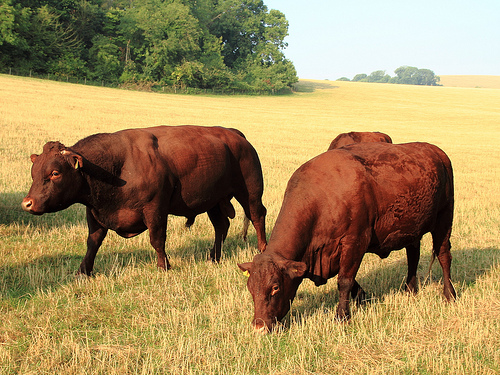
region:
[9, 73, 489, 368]
cows in the meadow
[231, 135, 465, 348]
cow is eating grass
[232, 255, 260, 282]
yellow tag on ear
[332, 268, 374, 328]
front legs of cow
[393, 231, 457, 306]
back legs of cow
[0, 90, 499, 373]
dry grass in the field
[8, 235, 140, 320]
shadow cast on the grass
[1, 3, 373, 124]
green trees on side of field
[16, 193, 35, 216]
nostrils of cow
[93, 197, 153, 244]
brisket of cow is bulky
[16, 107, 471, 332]
brown cows in a field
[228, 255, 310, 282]
the ears of cow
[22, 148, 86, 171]
the ears of cow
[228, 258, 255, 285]
a yellow tag on left ear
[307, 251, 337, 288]
brisket of cow is long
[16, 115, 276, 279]
the cow is walking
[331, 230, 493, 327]
a shadow below a cow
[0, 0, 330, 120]
green trees on side a field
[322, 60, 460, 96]
green bushes on the background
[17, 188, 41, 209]
Cow has tan nose.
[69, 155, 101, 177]
Yellow tag on cow's ear.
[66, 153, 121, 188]
Cow has brown ear.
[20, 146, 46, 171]
Cow has brown ear.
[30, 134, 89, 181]
Cow has brown head.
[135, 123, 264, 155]
Cow has brown back.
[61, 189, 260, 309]
Cow is standing on tall grass.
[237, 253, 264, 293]
Yellow tag on cow's ear.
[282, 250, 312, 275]
Cow has brown ear.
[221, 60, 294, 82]
Green trees in distance.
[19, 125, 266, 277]
a large brown cow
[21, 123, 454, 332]
the three cows are grazing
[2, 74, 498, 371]
a field of brown grass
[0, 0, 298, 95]
trees growing in a bunch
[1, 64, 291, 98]
a metal fence in front of the tress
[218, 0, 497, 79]
a clear blue sky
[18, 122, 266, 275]
the cow has a yellow tag in the left ear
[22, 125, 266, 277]
cow facing the left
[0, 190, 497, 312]
cow with it's face in the grass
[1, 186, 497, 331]
shadows on the ground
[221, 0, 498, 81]
a large area of blue sky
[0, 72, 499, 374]
a large field of golden grass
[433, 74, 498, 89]
a hill in the background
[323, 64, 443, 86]
a group of green trees in the background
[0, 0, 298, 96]
a large wooded area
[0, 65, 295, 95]
a fence around the wooded area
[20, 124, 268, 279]
a brown cow in the field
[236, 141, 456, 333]
a brown cow in the field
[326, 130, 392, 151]
a brown cow in the field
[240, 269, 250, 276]
a tag on the cow's ear